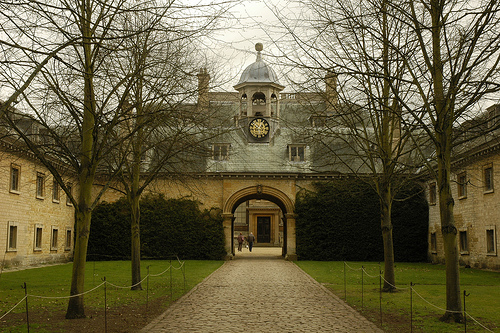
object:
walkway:
[132, 248, 394, 333]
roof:
[233, 42, 286, 88]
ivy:
[84, 190, 228, 263]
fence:
[0, 258, 188, 333]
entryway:
[222, 183, 298, 259]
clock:
[246, 116, 270, 140]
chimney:
[196, 62, 210, 105]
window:
[287, 142, 308, 164]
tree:
[0, 1, 261, 331]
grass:
[1, 260, 228, 333]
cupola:
[253, 42, 265, 60]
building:
[0, 97, 77, 271]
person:
[244, 231, 257, 252]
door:
[255, 214, 269, 244]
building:
[75, 44, 429, 261]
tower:
[233, 43, 284, 145]